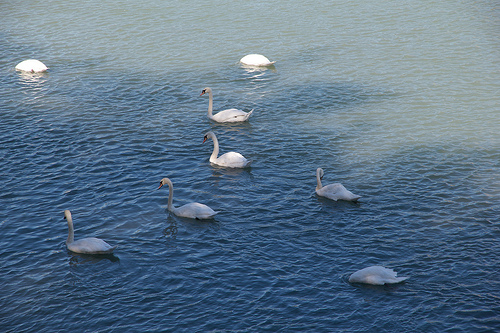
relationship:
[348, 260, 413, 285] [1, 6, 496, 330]
bird swimming in water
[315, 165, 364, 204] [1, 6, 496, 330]
bird swimming in water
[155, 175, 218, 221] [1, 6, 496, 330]
bird swimming in water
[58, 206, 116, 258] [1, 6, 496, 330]
bird swimming in water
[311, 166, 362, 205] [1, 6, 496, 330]
bird swimming in water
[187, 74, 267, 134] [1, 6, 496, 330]
birds swimming in water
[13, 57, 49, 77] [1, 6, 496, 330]
bird swimming in water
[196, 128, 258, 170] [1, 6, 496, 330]
bird swimming in water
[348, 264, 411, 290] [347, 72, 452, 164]
bird with head under water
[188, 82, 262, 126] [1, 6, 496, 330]
birds swimming in water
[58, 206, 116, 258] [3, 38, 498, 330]
bird swimming in shade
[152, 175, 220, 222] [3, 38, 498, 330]
bird swimming in shade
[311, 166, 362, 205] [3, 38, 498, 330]
bird swimming in shade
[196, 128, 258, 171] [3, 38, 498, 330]
bird swimming in shade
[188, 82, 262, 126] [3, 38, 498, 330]
birds swimming in shade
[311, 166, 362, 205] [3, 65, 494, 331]
bird swimming in shade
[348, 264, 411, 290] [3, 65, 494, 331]
bird swimming in shade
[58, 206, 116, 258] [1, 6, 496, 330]
bird in water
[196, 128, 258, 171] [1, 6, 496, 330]
bird with head under water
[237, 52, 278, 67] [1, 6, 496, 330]
bird with head under water